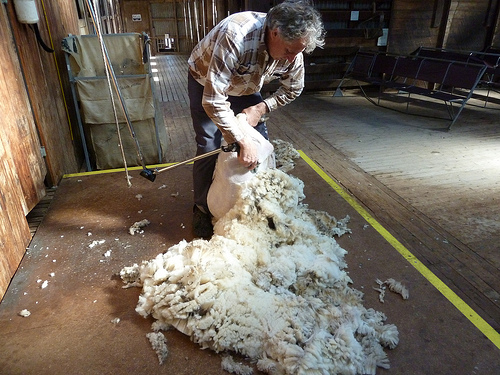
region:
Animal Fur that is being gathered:
[190, 211, 332, 343]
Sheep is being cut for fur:
[140, 133, 407, 368]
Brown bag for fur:
[51, 30, 171, 182]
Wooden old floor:
[366, 129, 490, 196]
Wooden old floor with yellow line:
[313, 145, 424, 271]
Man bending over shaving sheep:
[176, 0, 324, 228]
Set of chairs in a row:
[351, 40, 490, 142]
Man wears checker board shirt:
[179, 5, 376, 242]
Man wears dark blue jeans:
[179, 6, 330, 225]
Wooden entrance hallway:
[156, 12, 188, 137]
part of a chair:
[441, 100, 448, 105]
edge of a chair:
[424, 108, 431, 145]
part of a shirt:
[220, 115, 230, 131]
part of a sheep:
[288, 345, 303, 367]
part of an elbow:
[303, 91, 308, 93]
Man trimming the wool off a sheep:
[117, 1, 409, 373]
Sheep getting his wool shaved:
[206, 115, 275, 236]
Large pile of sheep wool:
[117, 145, 409, 373]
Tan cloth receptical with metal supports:
[60, 27, 167, 169]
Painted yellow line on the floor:
[293, 145, 498, 352]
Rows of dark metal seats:
[332, 45, 498, 135]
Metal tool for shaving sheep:
[85, 0, 261, 181]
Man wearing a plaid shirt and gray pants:
[184, 0, 324, 239]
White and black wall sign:
[130, 11, 143, 22]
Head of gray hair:
[268, 0, 328, 51]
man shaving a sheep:
[92, 11, 383, 364]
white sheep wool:
[157, 201, 355, 359]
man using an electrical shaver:
[137, 128, 271, 193]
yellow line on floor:
[285, 138, 472, 335]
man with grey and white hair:
[252, 0, 331, 60]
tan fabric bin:
[74, 23, 158, 166]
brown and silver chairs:
[328, 42, 494, 112]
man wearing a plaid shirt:
[171, 1, 326, 200]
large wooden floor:
[293, 72, 486, 234]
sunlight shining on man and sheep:
[195, 9, 327, 206]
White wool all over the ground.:
[120, 175, 400, 373]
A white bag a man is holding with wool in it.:
[207, 134, 274, 221]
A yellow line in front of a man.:
[298, 146, 498, 349]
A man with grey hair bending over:
[185, 0, 327, 240]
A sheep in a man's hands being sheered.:
[206, 112, 275, 223]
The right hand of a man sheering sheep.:
[240, 140, 260, 172]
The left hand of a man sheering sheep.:
[243, 105, 263, 126]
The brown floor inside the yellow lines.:
[2, 158, 497, 374]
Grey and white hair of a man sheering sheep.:
[266, 1, 326, 52]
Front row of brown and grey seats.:
[334, 43, 488, 134]